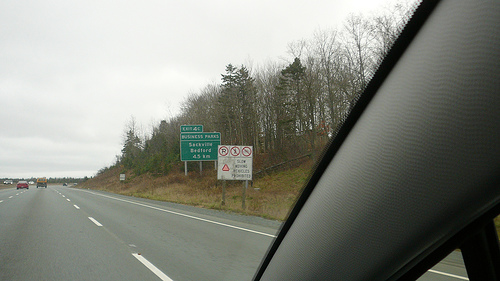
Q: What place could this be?
A: It is a highway.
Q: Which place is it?
A: It is a highway.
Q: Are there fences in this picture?
A: No, there are no fences.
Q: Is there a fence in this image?
A: No, there are no fences.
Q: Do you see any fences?
A: No, there are no fences.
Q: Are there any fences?
A: No, there are no fences.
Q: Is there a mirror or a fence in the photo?
A: No, there are no fences or mirrors.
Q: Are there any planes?
A: No, there are no planes.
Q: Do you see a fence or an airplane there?
A: No, there are no airplanes or fences.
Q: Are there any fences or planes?
A: No, there are no planes or fences.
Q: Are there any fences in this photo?
A: No, there are no fences.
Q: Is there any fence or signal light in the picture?
A: No, there are no fences or traffic lights.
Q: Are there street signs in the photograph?
A: Yes, there is a street sign.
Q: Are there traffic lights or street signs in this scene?
A: Yes, there is a street sign.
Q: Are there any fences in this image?
A: No, there are no fences.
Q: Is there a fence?
A: No, there are no fences.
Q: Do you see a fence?
A: No, there are no fences.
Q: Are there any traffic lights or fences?
A: No, there are no fences or traffic lights.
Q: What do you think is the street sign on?
A: The street sign is on the post.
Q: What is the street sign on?
A: The street sign is on the post.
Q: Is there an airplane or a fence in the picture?
A: No, there are no fences or airplanes.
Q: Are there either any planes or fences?
A: No, there are no fences or planes.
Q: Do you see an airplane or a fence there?
A: No, there are no fences or airplanes.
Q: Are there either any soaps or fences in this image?
A: No, there are no fences or soaps.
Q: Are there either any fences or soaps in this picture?
A: No, there are no fences or soaps.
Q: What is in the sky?
A: The clouds are in the sky.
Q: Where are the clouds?
A: The clouds are in the sky.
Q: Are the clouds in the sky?
A: Yes, the clouds are in the sky.